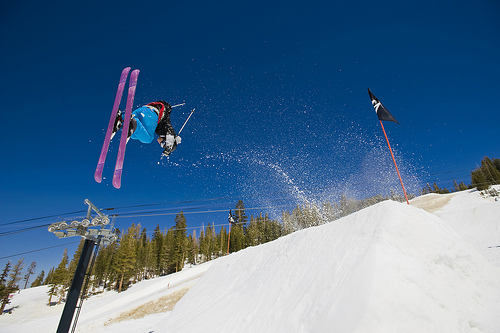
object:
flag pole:
[366, 88, 410, 206]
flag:
[367, 87, 400, 125]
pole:
[379, 121, 410, 206]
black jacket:
[146, 100, 182, 157]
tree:
[23, 260, 37, 289]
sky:
[6, 0, 227, 64]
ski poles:
[176, 107, 196, 135]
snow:
[0, 199, 499, 333]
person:
[111, 99, 182, 156]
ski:
[93, 66, 131, 184]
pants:
[121, 105, 159, 144]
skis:
[93, 66, 141, 190]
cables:
[0, 166, 498, 260]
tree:
[172, 210, 188, 275]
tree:
[160, 226, 175, 275]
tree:
[122, 222, 142, 292]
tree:
[234, 197, 249, 254]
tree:
[203, 223, 212, 261]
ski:
[111, 68, 140, 193]